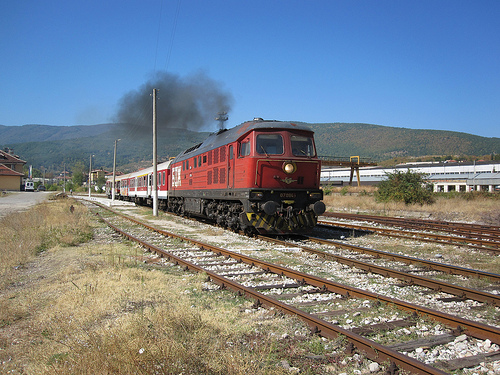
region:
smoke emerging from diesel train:
[101, 82, 224, 124]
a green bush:
[382, 170, 437, 203]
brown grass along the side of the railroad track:
[34, 206, 164, 372]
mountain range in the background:
[4, 123, 186, 150]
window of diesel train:
[254, 133, 286, 156]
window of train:
[290, 135, 313, 155]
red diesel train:
[169, 148, 327, 228]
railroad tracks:
[152, 228, 354, 332]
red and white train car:
[128, 166, 165, 196]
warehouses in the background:
[351, 169, 498, 196]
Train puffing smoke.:
[104, 66, 331, 241]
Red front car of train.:
[166, 116, 328, 238]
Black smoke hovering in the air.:
[112, 66, 232, 140]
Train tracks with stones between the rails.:
[75, 178, 497, 374]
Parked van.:
[26, 178, 34, 192]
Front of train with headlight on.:
[246, 114, 327, 239]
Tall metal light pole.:
[146, 88, 161, 221]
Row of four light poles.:
[60, 81, 160, 221]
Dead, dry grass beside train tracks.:
[0, 197, 498, 374]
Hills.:
[1, 121, 498, 173]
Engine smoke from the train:
[105, 77, 240, 144]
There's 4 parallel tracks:
[194, 221, 489, 317]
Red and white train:
[46, 107, 350, 250]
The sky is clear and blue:
[0, 6, 495, 141]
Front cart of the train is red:
[159, 125, 329, 232]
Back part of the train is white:
[96, 153, 175, 209]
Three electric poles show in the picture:
[59, 75, 193, 227]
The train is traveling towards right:
[9, 56, 489, 321]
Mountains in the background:
[1, 108, 495, 208]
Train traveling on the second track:
[0, 114, 480, 364]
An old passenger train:
[111, 117, 382, 233]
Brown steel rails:
[292, 272, 472, 363]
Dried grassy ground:
[43, 282, 194, 354]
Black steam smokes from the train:
[160, 80, 201, 122]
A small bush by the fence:
[374, 174, 445, 201]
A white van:
[21, 179, 38, 191]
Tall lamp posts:
[83, 147, 99, 199]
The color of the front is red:
[186, 153, 258, 185]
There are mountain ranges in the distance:
[360, 120, 461, 147]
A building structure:
[3, 147, 22, 191]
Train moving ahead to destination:
[106, 90, 386, 255]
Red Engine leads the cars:
[161, 120, 371, 241]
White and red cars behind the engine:
[103, 155, 176, 207]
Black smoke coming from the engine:
[111, 80, 297, 142]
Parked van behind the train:
[20, 173, 45, 193]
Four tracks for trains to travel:
[85, 190, 480, 320]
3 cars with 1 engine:
[92, 116, 382, 247]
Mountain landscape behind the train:
[7, 120, 497, 173]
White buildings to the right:
[358, 165, 491, 210]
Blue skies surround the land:
[39, 42, 425, 144]